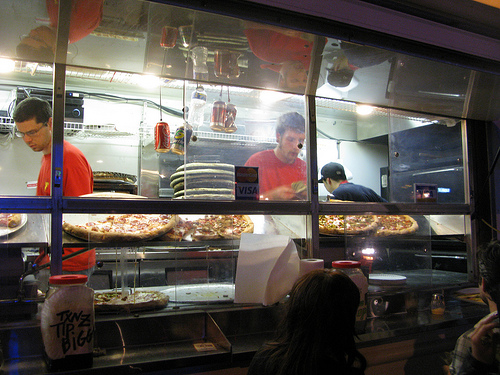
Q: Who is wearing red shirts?
A: Pizza employees.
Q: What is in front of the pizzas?
A: A window.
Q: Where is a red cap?
A: On top of tip jar.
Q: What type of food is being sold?
A: Pizza.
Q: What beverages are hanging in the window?
A: Soda and water.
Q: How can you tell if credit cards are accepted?
A: Mastercard and Visa sticker.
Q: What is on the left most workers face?
A: Glasses.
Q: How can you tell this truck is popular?
A: Customers waiting.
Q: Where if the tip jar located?
A: Outside serving window.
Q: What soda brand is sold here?
A: Coca Cola.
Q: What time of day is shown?
A: It is night time.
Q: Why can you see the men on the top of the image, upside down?
A: Reflection on metal.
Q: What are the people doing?
A: Working.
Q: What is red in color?
A: Worker's shirt.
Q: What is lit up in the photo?
A: The pizza place.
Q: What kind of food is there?
A: Pizza.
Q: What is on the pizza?
A: Toppings.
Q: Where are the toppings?
A: On the pizza.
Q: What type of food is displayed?
A: Pizza.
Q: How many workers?
A: Three.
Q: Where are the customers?
A: Outside the windows.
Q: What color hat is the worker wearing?
A: Black.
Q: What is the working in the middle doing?
A: Counting money.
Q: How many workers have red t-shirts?
A: Two.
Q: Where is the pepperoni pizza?
A: In the window.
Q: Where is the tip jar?
A: Outside ledge.